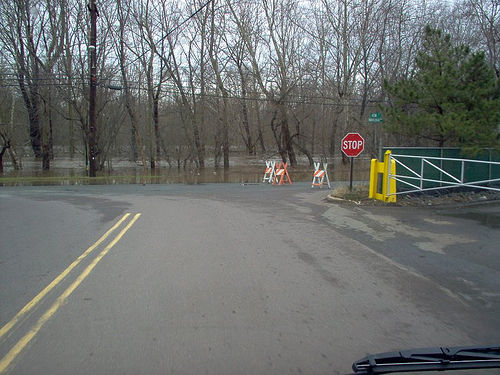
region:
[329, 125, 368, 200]
a red stop sign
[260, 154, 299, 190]
a construction barricade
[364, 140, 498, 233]
a driveway gate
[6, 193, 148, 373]
do not pass yellow centerlines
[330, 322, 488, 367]
a windshipled wiper blade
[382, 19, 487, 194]
a pine tree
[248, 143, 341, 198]
Barricades at a T intersection.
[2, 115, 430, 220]
T intersection with stop sign.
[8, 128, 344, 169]
Water in trees at edge of roadway.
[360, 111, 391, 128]
Street signs at the corner.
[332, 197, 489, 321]
Water on roadway.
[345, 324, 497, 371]
Window wiper on car.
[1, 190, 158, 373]
Yellow lines on roadway.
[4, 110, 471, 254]
Roadway ends at the waters edge.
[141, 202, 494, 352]
Roadway with edge of asphalt.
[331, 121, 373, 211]
STOP sign on corner of street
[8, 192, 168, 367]
two yellow lines on center of road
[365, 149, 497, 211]
a yellow and white rail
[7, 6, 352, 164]
trees with no leaves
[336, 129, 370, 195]
STOP sign is red and white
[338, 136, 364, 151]
letter STOP is white color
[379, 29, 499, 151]
tree with green leaves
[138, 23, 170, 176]
trunk of tree is thin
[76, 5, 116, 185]
pole is color black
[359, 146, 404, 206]
yellow hinge on gate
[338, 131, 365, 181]
red and white sign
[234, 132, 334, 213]
orange and white barriers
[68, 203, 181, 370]
yellow lines on road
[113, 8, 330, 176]
bare trees behind road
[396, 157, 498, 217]
silver gate near road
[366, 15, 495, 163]
green tree behind gate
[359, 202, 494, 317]
side of road is wet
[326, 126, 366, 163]
stop sign is octagonal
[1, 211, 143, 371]
Yellow stripes on a road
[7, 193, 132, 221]
Wet spot on a road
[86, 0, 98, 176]
A telephone pole by a streed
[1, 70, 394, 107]
Utility lines running off a pole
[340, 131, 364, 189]
A red stop sign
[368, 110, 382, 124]
A green street sign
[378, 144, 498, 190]
Green fence alongside road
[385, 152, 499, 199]
A metal entry gate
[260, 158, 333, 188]
Orage road signs in the street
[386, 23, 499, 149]
A green tree behind a fence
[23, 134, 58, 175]
Large tree in the water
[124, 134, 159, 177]
Large tree in the water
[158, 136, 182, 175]
Large tree in the water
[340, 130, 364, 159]
a red traffic stop sign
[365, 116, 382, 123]
a green street name sign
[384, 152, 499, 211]
a silver metal gate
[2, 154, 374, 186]
a flooded area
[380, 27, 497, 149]
a large green tree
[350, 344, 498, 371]
a black windshield wiper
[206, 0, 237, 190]
A tree in the woods.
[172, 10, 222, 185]
A tree in the woods.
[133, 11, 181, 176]
A tree in the woods.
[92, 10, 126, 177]
A tree in the woods.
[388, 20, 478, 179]
A tree in the woods.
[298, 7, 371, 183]
A tree in the woods.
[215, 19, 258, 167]
A tree in the woods.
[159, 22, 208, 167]
A tree in the woods.